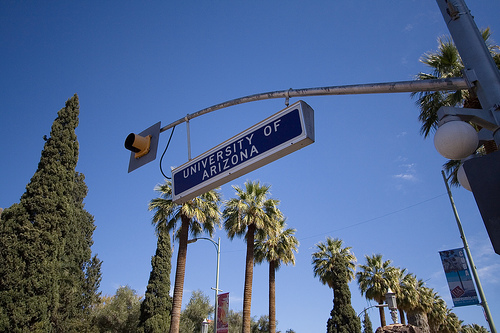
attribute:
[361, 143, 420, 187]
cloud — small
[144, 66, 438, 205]
sky — blue, clear, cloudless, beautiful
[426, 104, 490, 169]
light — white, round, globe, grey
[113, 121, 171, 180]
light — traffic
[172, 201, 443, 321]
trees — green, tall, narrow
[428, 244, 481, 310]
banner — blue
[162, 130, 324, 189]
sign — white, blue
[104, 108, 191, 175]
traffic light — alert, grey, yellow, metal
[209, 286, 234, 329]
sign — red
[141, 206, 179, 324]
pine tree — skinny, tall, narrow, triangle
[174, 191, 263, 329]
palm trees — lined, green, yellow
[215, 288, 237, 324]
flag — decorative, red, white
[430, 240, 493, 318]
flag — decorative, white, blue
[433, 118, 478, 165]
lamp — round, white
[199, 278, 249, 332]
banner — red